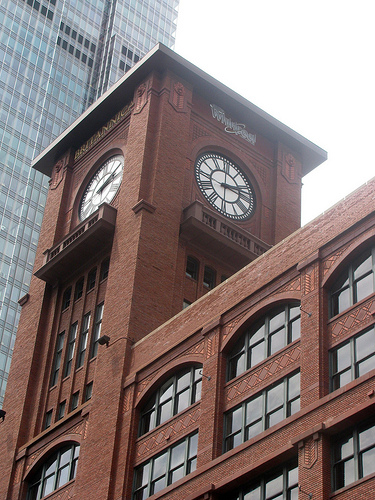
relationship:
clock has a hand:
[193, 152, 256, 221] [220, 178, 258, 197]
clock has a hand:
[193, 152, 256, 221] [223, 185, 250, 202]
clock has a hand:
[79, 149, 124, 213] [98, 164, 121, 183]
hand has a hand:
[220, 178, 258, 197] [94, 171, 120, 194]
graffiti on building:
[211, 107, 257, 145] [6, 40, 370, 496]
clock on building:
[193, 152, 256, 221] [6, 40, 370, 496]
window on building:
[123, 359, 202, 495] [37, 226, 334, 469]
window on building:
[220, 280, 310, 459] [37, 226, 334, 469]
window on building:
[318, 252, 364, 397] [37, 226, 334, 469]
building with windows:
[10, 61, 374, 374] [57, 281, 77, 313]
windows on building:
[57, 281, 77, 313] [10, 61, 374, 374]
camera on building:
[96, 333, 122, 346] [18, 72, 374, 492]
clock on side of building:
[193, 152, 256, 221] [0, 39, 373, 498]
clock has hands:
[78, 154, 123, 225] [97, 163, 124, 177]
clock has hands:
[193, 152, 256, 221] [97, 163, 124, 177]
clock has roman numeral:
[193, 152, 256, 221] [209, 156, 227, 170]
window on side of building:
[123, 424, 202, 496] [6, 40, 370, 496]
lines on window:
[270, 382, 299, 408] [221, 368, 300, 455]